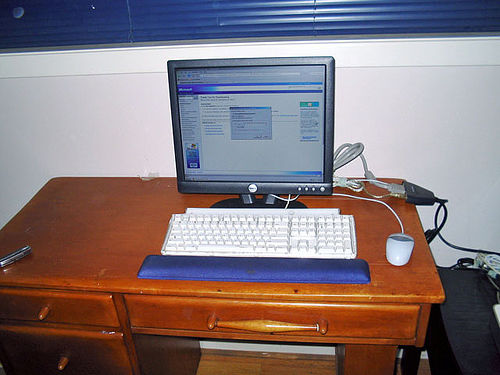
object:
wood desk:
[0, 167, 447, 375]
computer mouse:
[384, 232, 414, 267]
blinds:
[0, 0, 498, 54]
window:
[0, 0, 496, 55]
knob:
[37, 307, 49, 320]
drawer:
[2, 289, 120, 328]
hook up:
[401, 177, 500, 256]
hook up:
[332, 141, 406, 202]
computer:
[160, 56, 357, 259]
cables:
[269, 142, 500, 291]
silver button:
[246, 183, 257, 193]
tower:
[425, 262, 498, 375]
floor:
[197, 346, 433, 375]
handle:
[207, 316, 327, 335]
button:
[320, 185, 327, 192]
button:
[312, 187, 315, 191]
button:
[304, 187, 308, 191]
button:
[297, 186, 302, 191]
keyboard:
[161, 207, 358, 260]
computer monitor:
[164, 55, 337, 198]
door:
[0, 325, 131, 375]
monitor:
[174, 64, 324, 184]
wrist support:
[136, 252, 370, 285]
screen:
[175, 66, 327, 184]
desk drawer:
[119, 295, 422, 342]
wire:
[269, 143, 498, 295]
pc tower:
[425, 265, 498, 375]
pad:
[133, 254, 370, 286]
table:
[2, 177, 445, 375]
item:
[0, 244, 32, 270]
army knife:
[0, 244, 34, 268]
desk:
[0, 175, 447, 375]